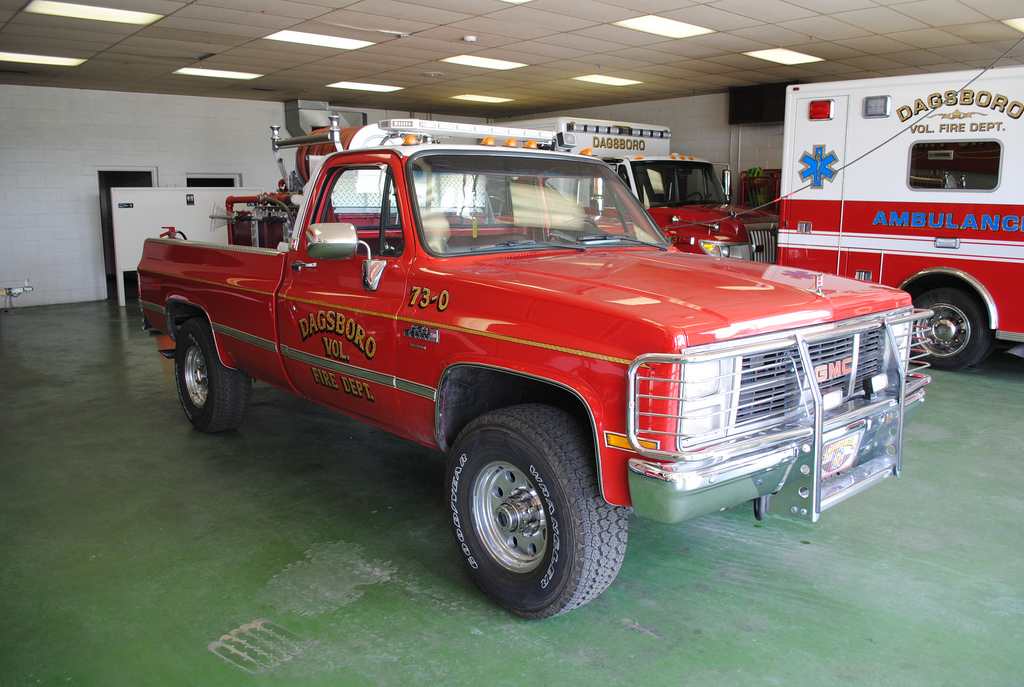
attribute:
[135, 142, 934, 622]
truck — red, parked, for emergencies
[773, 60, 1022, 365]
ambulance — red, white, a truck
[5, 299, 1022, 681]
floor — green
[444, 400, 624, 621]
tire — large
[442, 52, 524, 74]
light — a rectangle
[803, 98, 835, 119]
light — unlit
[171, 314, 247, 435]
tire — white